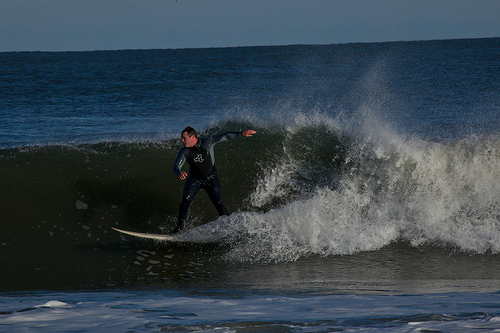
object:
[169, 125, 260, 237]
man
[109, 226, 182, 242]
surfboard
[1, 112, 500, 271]
wave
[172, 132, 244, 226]
wet suit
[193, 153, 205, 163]
logo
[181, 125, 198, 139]
hair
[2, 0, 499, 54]
sky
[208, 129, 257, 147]
left arm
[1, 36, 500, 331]
water